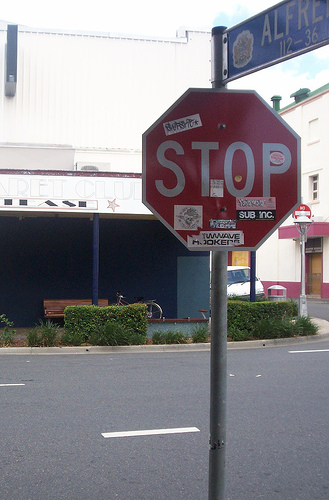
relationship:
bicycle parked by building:
[108, 293, 163, 319] [14, 145, 195, 301]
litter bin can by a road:
[267, 282, 288, 298] [246, 348, 313, 462]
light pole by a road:
[295, 241, 322, 310] [246, 348, 313, 462]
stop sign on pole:
[148, 90, 328, 230] [195, 259, 244, 499]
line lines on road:
[94, 426, 203, 439] [57, 361, 317, 413]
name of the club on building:
[10, 178, 161, 195] [16, 72, 141, 133]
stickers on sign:
[170, 121, 288, 228] [139, 87, 298, 260]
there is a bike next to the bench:
[95, 285, 195, 313] [26, 292, 112, 321]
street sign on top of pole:
[215, 0, 327, 79] [208, 271, 243, 392]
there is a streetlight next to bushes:
[169, 123, 212, 194] [58, 290, 168, 338]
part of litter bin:
[271, 283, 291, 299] [270, 277, 288, 298]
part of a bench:
[44, 295, 106, 314] [33, 292, 111, 303]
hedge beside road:
[231, 300, 304, 336] [57, 361, 317, 413]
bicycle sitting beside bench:
[104, 295, 172, 306] [33, 292, 111, 303]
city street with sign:
[133, 11, 324, 235] [139, 87, 298, 260]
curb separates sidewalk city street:
[300, 306, 327, 348] [133, 11, 324, 347]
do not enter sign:
[294, 201, 315, 221] [148, 90, 328, 230]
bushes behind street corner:
[231, 300, 324, 336] [313, 299, 323, 348]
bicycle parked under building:
[108, 293, 173, 312] [19, 215, 170, 293]